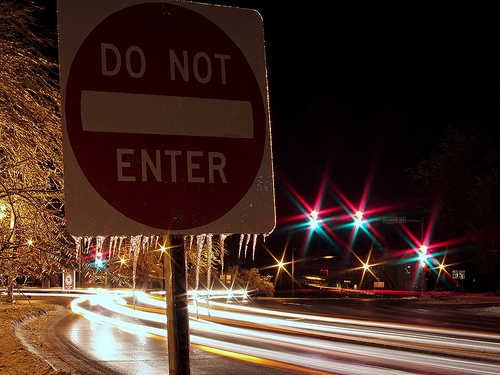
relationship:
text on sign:
[97, 41, 233, 90] [57, 1, 287, 374]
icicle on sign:
[197, 231, 208, 288] [57, 1, 287, 374]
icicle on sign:
[128, 240, 138, 278] [57, 1, 287, 374]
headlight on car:
[189, 286, 199, 299] [186, 281, 217, 307]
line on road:
[214, 347, 272, 367] [215, 295, 417, 374]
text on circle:
[97, 41, 233, 90] [118, 11, 194, 46]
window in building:
[318, 267, 333, 282] [305, 254, 478, 292]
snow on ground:
[19, 327, 27, 340] [1, 304, 21, 374]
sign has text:
[57, 1, 287, 374] [97, 41, 233, 90]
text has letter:
[97, 41, 233, 90] [217, 51, 236, 94]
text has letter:
[207, 151, 230, 187] [207, 152, 226, 186]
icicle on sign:
[72, 239, 87, 253] [57, 1, 287, 374]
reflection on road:
[85, 319, 130, 359] [215, 295, 417, 374]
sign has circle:
[57, 1, 287, 374] [118, 11, 194, 46]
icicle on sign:
[219, 237, 229, 266] [57, 1, 287, 374]